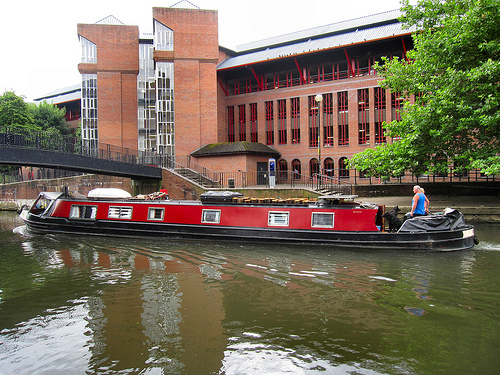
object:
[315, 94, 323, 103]
light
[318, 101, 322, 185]
post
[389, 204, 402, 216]
dogs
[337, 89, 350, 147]
window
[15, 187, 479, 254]
boat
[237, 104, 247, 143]
window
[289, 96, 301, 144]
window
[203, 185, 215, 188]
steps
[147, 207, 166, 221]
window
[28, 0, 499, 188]
building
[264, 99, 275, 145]
window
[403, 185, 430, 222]
man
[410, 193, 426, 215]
blue top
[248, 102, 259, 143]
window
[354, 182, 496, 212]
pavement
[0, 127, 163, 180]
bridge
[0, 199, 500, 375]
lake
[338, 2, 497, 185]
tree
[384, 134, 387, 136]
leaves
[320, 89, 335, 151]
window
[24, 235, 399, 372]
reflection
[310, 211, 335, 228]
window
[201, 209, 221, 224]
window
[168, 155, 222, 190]
stairs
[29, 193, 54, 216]
windows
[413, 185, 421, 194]
head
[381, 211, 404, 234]
black dog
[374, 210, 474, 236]
deck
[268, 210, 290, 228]
window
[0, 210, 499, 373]
water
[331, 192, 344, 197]
steps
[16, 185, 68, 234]
cabin area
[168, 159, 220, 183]
rails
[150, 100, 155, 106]
windows